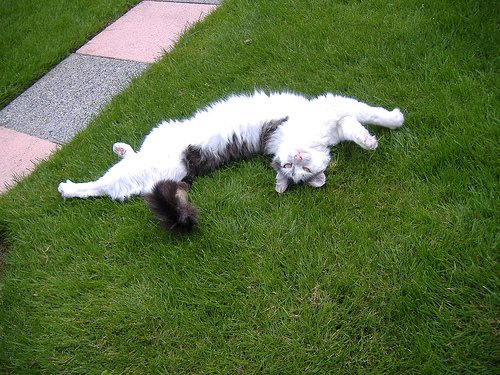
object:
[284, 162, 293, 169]
eyes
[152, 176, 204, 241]
tail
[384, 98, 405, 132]
paw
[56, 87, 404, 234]
cat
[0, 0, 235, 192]
made of tiles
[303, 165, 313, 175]
eyes are yellow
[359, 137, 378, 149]
claws are white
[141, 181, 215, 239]
tail is black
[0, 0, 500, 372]
day time picture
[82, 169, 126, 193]
back leg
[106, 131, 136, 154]
paw of a cat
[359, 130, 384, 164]
paw of  cat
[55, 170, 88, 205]
paw of a cat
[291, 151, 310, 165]
pink nose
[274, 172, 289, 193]
ear of a cat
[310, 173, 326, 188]
ear of a cat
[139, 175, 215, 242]
tail of a cat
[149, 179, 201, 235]
bushy tail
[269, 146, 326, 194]
cat is looking up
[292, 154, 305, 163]
cats nose pink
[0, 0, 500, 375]
grass is green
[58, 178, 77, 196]
cat has white feet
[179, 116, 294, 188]
black on its back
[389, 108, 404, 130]
cat has pink paws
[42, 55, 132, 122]
sidewalk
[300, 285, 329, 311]
clump of dry grass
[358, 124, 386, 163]
paw of cat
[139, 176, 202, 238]
tail of cat on grass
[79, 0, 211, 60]
tile on grass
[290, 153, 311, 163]
pink nose on cat